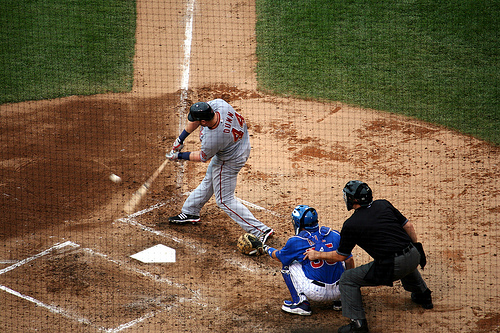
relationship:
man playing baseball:
[123, 99, 275, 257] [105, 173, 122, 183]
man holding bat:
[123, 99, 275, 257] [122, 142, 177, 214]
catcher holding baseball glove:
[260, 201, 356, 318] [235, 233, 265, 259]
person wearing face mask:
[300, 184, 440, 332] [341, 182, 374, 211]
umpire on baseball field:
[300, 184, 440, 332] [2, 4, 499, 331]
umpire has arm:
[300, 184, 440, 332] [300, 247, 352, 265]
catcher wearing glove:
[260, 201, 356, 318] [235, 233, 265, 259]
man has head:
[123, 99, 275, 257] [189, 104, 226, 134]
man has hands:
[123, 99, 275, 257] [161, 137, 182, 159]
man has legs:
[123, 99, 275, 257] [171, 159, 275, 246]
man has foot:
[123, 99, 275, 257] [170, 208, 206, 229]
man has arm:
[300, 184, 440, 332] [300, 247, 352, 265]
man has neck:
[123, 99, 275, 257] [208, 108, 221, 130]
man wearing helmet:
[123, 99, 275, 257] [187, 102, 214, 124]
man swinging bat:
[123, 99, 275, 257] [122, 142, 177, 214]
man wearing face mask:
[300, 184, 440, 332] [341, 182, 374, 211]